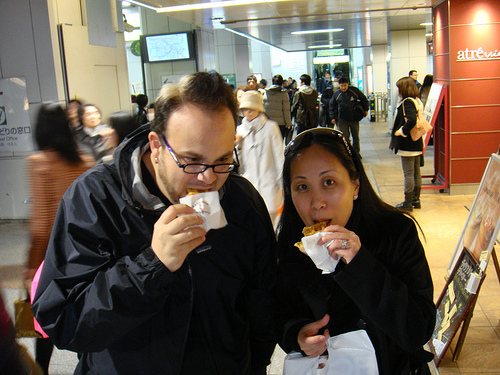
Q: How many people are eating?
A: 2.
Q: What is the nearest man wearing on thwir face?
A: Glasses.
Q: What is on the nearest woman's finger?
A: Ring.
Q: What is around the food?
A: Paper.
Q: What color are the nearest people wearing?
A: Black.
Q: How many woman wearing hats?
A: 1.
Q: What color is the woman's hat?
A: Cream.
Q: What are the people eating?
A: Waffles.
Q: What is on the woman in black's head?
A: Sunglasses.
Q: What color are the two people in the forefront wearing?
A: Black.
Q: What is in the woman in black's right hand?
A: A shopping bag.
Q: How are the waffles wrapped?
A: In paper.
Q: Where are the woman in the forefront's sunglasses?
A: On her head.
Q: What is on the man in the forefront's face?
A: Glasses.